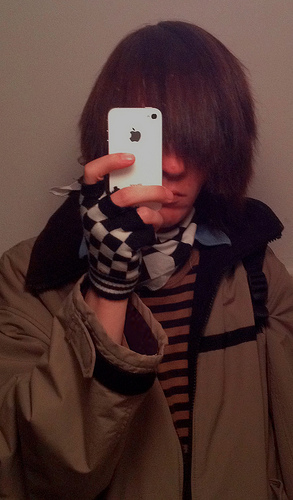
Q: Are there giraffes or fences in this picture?
A: No, there are no fences or giraffes.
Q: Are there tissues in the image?
A: No, there are no tissues.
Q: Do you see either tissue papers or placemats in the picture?
A: No, there are no tissue papers or placemats.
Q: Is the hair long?
A: Yes, the hair is long.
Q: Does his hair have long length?
A: Yes, the hair is long.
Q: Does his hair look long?
A: Yes, the hair is long.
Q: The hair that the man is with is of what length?
A: The hair is long.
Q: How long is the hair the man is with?
A: The hair is long.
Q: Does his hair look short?
A: No, the hair is long.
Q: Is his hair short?
A: No, the hair is long.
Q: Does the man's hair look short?
A: No, the hair is long.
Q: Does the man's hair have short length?
A: No, the hair is long.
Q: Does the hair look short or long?
A: The hair is long.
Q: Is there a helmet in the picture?
A: No, there are no helmets.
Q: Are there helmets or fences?
A: No, there are no helmets or fences.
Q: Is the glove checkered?
A: Yes, the glove is checkered.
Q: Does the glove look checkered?
A: Yes, the glove is checkered.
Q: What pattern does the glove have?
A: The glove has checkered pattern.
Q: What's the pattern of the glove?
A: The glove is checkered.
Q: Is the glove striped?
A: No, the glove is checkered.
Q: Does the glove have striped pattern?
A: No, the glove is checkered.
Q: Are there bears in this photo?
A: No, there are no bears.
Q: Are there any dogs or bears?
A: No, there are no bears or dogs.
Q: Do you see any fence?
A: No, there are no fences.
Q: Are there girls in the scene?
A: No, there are no girls.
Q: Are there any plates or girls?
A: No, there are no girls or plates.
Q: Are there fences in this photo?
A: No, there are no fences.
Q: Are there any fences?
A: No, there are no fences.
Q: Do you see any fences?
A: No, there are no fences.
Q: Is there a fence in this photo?
A: No, there are no fences.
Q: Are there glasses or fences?
A: No, there are no fences or glasses.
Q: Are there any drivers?
A: No, there are no drivers.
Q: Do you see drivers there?
A: No, there are no drivers.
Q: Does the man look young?
A: Yes, the man is young.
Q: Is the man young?
A: Yes, the man is young.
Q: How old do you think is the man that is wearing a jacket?
A: The man is young.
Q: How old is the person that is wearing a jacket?
A: The man is young.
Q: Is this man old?
A: No, the man is young.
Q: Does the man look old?
A: No, the man is young.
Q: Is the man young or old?
A: The man is young.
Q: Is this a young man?
A: Yes, this is a young man.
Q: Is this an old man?
A: No, this is a young man.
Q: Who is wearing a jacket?
A: The man is wearing a jacket.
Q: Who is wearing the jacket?
A: The man is wearing a jacket.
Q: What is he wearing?
A: The man is wearing a jacket.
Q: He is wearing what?
A: The man is wearing a jacket.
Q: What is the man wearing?
A: The man is wearing a jacket.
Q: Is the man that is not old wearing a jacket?
A: Yes, the man is wearing a jacket.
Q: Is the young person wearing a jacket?
A: Yes, the man is wearing a jacket.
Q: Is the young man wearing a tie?
A: No, the man is wearing a jacket.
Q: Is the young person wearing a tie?
A: No, the man is wearing a jacket.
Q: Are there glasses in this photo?
A: No, there are no glasses.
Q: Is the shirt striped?
A: Yes, the shirt is striped.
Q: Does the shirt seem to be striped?
A: Yes, the shirt is striped.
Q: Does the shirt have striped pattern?
A: Yes, the shirt is striped.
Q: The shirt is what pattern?
A: The shirt is striped.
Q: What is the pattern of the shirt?
A: The shirt is striped.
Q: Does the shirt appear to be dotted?
A: No, the shirt is striped.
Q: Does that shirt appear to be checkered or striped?
A: The shirt is striped.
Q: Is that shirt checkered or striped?
A: The shirt is striped.